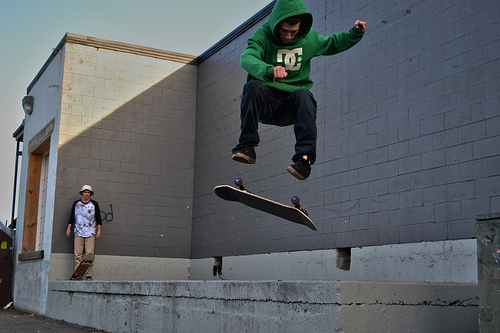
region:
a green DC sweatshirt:
[238, 1, 367, 92]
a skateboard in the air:
[206, 176, 324, 236]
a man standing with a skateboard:
[65, 184, 104, 281]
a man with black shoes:
[228, 143, 318, 183]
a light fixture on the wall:
[19, 94, 36, 115]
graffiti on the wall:
[97, 201, 115, 225]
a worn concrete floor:
[47, 278, 499, 332]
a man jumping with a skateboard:
[213, 1, 368, 232]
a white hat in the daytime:
[75, 182, 96, 196]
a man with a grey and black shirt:
[66, 186, 101, 281]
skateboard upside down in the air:
[213, 178, 316, 230]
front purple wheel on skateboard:
[290, 191, 300, 207]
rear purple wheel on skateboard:
[233, 175, 242, 187]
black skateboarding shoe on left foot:
[282, 153, 313, 180]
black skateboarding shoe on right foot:
[228, 142, 254, 160]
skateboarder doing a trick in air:
[210, 2, 365, 233]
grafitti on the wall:
[99, 202, 118, 223]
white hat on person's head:
[81, 182, 96, 193]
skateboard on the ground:
[72, 254, 94, 282]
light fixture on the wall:
[23, 94, 38, 119]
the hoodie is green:
[237, 5, 367, 120]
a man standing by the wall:
[50, 160, 129, 274]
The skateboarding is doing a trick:
[218, 3, 402, 258]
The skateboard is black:
[205, 173, 319, 240]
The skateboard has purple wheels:
[230, 173, 306, 205]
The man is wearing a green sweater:
[250, 7, 357, 106]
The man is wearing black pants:
[242, 68, 329, 166]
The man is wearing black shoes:
[230, 140, 318, 185]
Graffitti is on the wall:
[96, 199, 120, 226]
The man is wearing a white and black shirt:
[69, 195, 103, 240]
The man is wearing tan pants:
[70, 230, 97, 273]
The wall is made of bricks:
[73, 61, 181, 188]